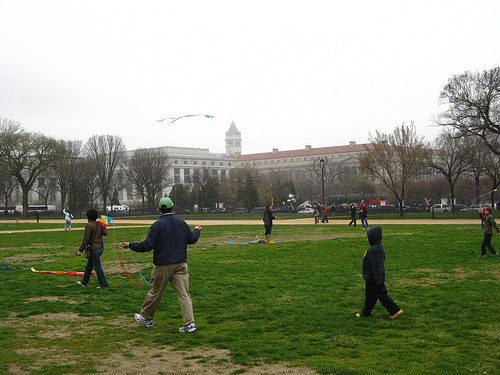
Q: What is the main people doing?
A: Flying kites.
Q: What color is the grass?
A: Green.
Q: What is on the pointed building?
A: Clocks.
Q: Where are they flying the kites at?
A: Park.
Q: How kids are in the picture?
A: 1.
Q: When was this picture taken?
A: Daytime.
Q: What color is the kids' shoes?
A: Yellow.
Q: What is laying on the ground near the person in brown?
A: Kite.